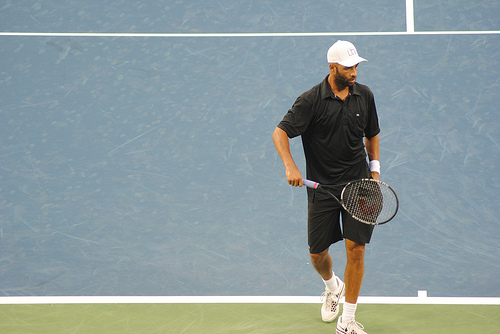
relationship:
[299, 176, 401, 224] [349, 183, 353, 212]
racket with string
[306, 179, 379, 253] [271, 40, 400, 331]
shorts on a man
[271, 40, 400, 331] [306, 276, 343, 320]
man wearing to shoes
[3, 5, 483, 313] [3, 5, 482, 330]
white boundary on tennis-courts surface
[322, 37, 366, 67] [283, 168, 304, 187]
cap on a hand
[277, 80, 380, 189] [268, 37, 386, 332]
black shirt on a tennis player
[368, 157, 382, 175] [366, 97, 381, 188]
white wristband on a man's arm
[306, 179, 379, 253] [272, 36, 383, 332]
shorts on a man's feet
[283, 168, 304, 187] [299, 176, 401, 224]
hand gripping a racket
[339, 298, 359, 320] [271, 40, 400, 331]
white sock on a man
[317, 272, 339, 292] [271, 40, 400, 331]
white sock on a man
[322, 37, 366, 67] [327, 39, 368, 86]
cap on a head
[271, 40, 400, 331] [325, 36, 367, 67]
man playing tennis in a white cap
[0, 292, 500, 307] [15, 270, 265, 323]
white line separating blue-from-green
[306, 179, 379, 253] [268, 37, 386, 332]
shorts on a tennis player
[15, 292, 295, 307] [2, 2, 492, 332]
white line on court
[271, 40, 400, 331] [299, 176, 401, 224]
man holding racket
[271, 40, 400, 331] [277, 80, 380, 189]
man wearing black shirt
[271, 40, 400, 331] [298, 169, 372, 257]
man wearing shorts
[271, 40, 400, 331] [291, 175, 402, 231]
man holding racket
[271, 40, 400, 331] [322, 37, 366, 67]
man wearing cap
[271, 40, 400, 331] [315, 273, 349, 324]
man wearing shoes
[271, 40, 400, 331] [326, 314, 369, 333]
man wearing shoes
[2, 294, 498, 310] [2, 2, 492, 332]
lines on court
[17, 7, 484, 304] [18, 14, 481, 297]
wall on side of a building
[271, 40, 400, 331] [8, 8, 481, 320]
man standing on field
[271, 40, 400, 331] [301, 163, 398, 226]
man standing holding a racket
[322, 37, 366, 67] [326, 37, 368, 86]
cap on head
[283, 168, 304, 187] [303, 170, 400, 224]
hand holding racket